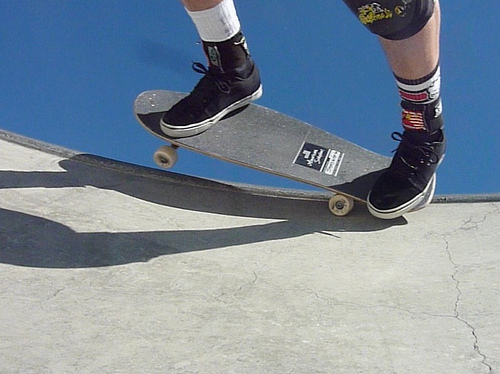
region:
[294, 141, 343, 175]
product sticker on skateboard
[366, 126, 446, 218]
black tennis shoe on foot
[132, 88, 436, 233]
skateboard on edge of pool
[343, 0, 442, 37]
bottom hem of shorts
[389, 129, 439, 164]
shoelaces on shoe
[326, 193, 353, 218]
white wheel on skateboard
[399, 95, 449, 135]
ankle brace on leg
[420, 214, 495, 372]
crack running in cement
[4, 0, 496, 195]
blue insides of empty pool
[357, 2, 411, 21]
logo on shorts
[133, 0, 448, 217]
Man on a skateboard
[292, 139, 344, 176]
Black and white sticker on a skateboard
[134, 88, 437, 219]
Black skateboard with white wheels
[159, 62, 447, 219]
Pair of black shoes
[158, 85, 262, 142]
White rubber sole of a shoe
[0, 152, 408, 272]
Shadow of a man on a skateboard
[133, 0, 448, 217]
Person riding a skateboard on a ramp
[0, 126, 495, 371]
Gray concrete skating ramp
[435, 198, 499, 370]
Large cracks in a skate ramp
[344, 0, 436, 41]
Black kneepad with yellow letters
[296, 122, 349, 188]
There is a sticker that is on the skateboard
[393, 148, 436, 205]
There is a black shoe that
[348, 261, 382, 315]
There is a black patch of asphalt here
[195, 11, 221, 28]
There is a pair of white socks here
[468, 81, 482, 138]
There is a dark blue sky that is here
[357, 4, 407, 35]
There is a knee pad that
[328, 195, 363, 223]
There is a white wheel here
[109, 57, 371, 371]
This photo has a great amount of detail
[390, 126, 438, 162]
shoe laces on man foot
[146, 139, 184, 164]
wheel on skateboard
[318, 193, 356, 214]
wheel on skateboard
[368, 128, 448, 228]
shoe on man's foot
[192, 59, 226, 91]
shoe lace on the shoe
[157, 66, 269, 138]
black shoe on man's foot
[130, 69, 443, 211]
skateboard on the ledge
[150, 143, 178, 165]
white wheel on the skateboard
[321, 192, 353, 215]
white wheel on the skateboard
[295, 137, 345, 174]
design on the skateboard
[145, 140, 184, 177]
A skateboard wheel is white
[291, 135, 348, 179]
A black and white sticker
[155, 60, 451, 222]
A pair of black sneakers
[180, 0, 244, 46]
A white colored sock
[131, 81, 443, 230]
Two feet on a skateboard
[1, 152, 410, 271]
A shadow on the ground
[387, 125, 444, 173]
Black laces on a sneaker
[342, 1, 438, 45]
A black knee pad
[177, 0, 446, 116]
A pair of two legs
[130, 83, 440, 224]
A black skateboard with white wheels